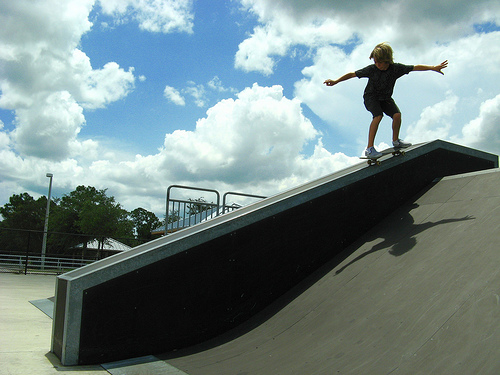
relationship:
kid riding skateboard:
[319, 40, 451, 158] [359, 141, 411, 165]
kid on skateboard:
[319, 40, 451, 158] [359, 141, 411, 165]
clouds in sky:
[1, 1, 141, 162] [3, 2, 499, 230]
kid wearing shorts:
[319, 40, 451, 158] [360, 95, 404, 117]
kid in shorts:
[319, 40, 451, 158] [360, 95, 404, 117]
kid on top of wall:
[319, 40, 451, 158] [41, 139, 497, 365]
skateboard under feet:
[359, 141, 411, 165] [362, 140, 414, 157]